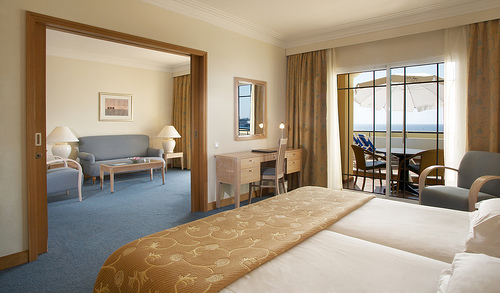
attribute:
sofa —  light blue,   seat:
[78, 135, 165, 187]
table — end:
[164, 152, 184, 169]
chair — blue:
[417, 148, 497, 209]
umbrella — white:
[348, 71, 445, 117]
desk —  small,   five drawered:
[206, 146, 312, 213]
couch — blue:
[69, 127, 172, 182]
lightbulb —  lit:
[274, 111, 291, 134]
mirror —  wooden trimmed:
[238, 80, 263, 136]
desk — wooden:
[212, 145, 308, 211]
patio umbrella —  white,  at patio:
[361, 79, 438, 114]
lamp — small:
[266, 118, 293, 149]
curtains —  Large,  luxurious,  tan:
[292, 20, 497, 192]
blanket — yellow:
[89, 178, 379, 291]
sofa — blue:
[77, 136, 164, 180]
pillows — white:
[441, 181, 494, 291]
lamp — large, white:
[49, 124, 85, 161]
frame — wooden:
[229, 73, 273, 146]